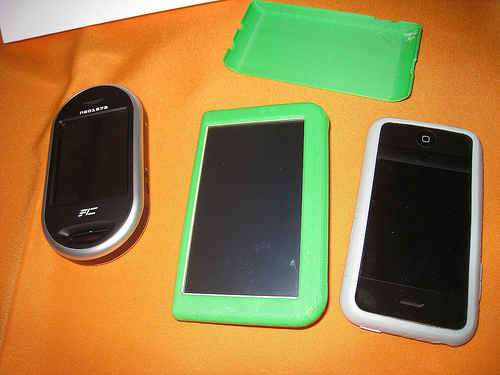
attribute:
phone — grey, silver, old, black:
[41, 83, 151, 263]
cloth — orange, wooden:
[2, 2, 496, 373]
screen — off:
[52, 106, 133, 209]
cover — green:
[220, 1, 422, 105]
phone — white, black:
[339, 114, 481, 348]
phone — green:
[169, 100, 331, 329]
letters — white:
[77, 103, 111, 117]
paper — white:
[1, 2, 223, 45]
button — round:
[416, 128, 438, 148]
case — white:
[340, 116, 485, 349]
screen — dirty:
[181, 113, 307, 306]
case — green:
[169, 98, 331, 329]